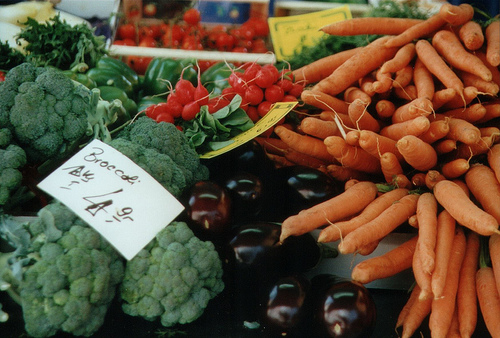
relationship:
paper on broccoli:
[36, 137, 186, 260] [10, 67, 88, 152]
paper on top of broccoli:
[36, 137, 186, 260] [10, 67, 88, 152]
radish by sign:
[176, 61, 196, 104] [266, 6, 351, 62]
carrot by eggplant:
[431, 179, 499, 234] [176, 175, 236, 246]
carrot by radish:
[431, 179, 499, 234] [176, 61, 196, 104]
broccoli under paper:
[10, 67, 88, 152] [36, 137, 186, 260]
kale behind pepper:
[184, 89, 243, 149] [214, 33, 237, 54]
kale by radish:
[184, 89, 243, 149] [176, 61, 196, 104]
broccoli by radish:
[10, 67, 88, 152] [176, 61, 196, 104]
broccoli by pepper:
[10, 67, 88, 152] [214, 33, 237, 54]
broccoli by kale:
[10, 67, 88, 152] [184, 89, 243, 149]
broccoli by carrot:
[10, 67, 88, 152] [431, 179, 499, 234]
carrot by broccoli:
[431, 179, 499, 234] [10, 67, 88, 152]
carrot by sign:
[431, 179, 499, 234] [266, 6, 351, 62]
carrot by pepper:
[431, 179, 499, 234] [214, 33, 237, 54]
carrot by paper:
[431, 179, 499, 234] [36, 137, 186, 260]